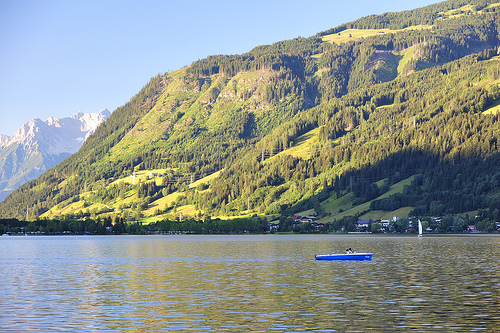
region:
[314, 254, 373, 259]
The blue boat in the water.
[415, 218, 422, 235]
The white sail on the boat.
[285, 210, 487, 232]
The houses in the background.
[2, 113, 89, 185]
The mountains in the background.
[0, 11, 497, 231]
The green hill behind the houses.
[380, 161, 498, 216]
The trees on the right.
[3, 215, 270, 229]
The trees on the left.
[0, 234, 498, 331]
The water in the area.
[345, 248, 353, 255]
The people on the blue boat.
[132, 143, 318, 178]
The wires on the hill.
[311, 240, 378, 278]
Blue canoe in the water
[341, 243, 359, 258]
person inside the canoe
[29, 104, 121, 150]
snow on the mountain top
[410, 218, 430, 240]
sailboat on the water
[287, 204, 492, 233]
Houses on the water edge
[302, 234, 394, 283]
boat in the water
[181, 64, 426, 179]
trees on the mountain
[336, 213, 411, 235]
house surrounded by trees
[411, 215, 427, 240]
white sailboat on the water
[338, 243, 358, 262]
people in the water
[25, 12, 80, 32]
this is the sky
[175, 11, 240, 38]
the sky is blue in color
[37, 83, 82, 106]
the sky has clouds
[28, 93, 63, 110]
the clouds are white in color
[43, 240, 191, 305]
this is the water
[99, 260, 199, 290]
the water has ripples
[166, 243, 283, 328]
the ripples are big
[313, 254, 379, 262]
this is a boat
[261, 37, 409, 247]
this is a hill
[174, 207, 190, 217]
the grass is green in color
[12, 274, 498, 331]
the water is dark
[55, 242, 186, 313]
the water is calm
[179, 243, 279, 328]
the water is still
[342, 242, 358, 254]
the people are in a boat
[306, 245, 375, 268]
the boat is blue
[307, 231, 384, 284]
the boat is in the water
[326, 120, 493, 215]
the shadow is on the mountain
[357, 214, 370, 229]
the house is on the bottom of the hill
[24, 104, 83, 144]
the snow is on the top of the mountain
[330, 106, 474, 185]
the trees are growing on the side of the mountain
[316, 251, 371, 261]
blue boat in lake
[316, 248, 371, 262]
boat floating in lake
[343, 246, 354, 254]
people sitting in boat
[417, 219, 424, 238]
sale boat in lake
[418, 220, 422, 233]
white sail on boat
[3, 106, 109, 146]
snow covered mountain top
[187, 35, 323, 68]
green trees on mountain top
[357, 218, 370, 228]
white and grey house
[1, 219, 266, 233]
green trees by lake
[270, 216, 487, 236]
houses next to lake